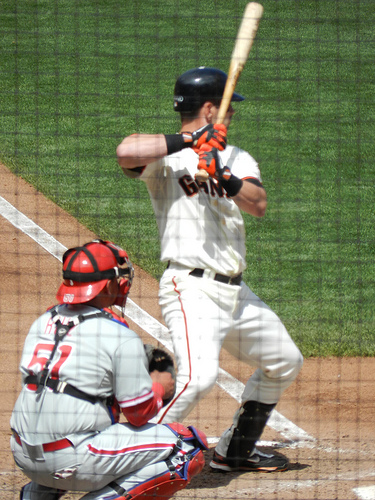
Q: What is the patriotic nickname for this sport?
A: America's pastime.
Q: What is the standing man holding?
A: Bat.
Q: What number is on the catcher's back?
A: 51.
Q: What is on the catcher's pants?
A: Red belt.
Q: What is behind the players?
A: Net.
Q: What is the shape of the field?
A: Diamond.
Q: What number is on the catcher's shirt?
A: 51.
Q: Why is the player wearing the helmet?
A: For protection.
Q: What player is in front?
A: Batter.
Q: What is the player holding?
A: Baseball bat.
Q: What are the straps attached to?
A: Chest protector.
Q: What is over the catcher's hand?
A: Mitt.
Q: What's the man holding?
A: Bat.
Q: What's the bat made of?
A: Wood.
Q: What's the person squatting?
A: Catcher.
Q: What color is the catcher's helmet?
A: Red.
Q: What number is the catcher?
A: 51.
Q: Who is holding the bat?
A: The batter.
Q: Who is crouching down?
A: The catcher.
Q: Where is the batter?
A: In front of the catcher.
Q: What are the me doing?
A: Playing baseball.